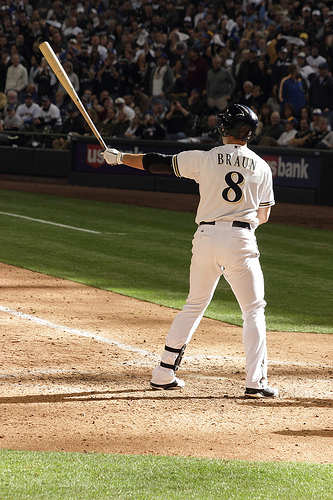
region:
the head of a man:
[212, 98, 262, 147]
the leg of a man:
[226, 249, 270, 384]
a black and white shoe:
[243, 382, 283, 399]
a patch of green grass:
[1, 446, 332, 498]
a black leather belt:
[195, 217, 254, 227]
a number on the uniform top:
[217, 167, 248, 204]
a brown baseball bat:
[37, 37, 113, 147]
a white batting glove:
[96, 142, 125, 169]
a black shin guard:
[158, 337, 190, 371]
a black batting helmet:
[212, 99, 259, 142]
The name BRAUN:
[213, 151, 265, 170]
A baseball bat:
[32, 36, 124, 171]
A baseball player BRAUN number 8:
[212, 151, 258, 212]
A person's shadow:
[0, 367, 322, 415]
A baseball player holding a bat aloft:
[32, 35, 296, 233]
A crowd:
[67, 0, 332, 92]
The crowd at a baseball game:
[1, 17, 332, 239]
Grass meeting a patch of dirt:
[5, 441, 331, 499]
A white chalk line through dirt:
[1, 306, 139, 373]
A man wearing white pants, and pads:
[147, 217, 279, 402]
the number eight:
[220, 168, 243, 203]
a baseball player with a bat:
[40, 42, 275, 397]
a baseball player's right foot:
[246, 384, 275, 400]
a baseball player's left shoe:
[150, 376, 186, 391]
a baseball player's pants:
[150, 220, 266, 389]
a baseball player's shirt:
[173, 141, 274, 223]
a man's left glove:
[98, 147, 121, 163]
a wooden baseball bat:
[37, 39, 108, 149]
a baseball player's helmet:
[216, 103, 257, 141]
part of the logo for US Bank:
[84, 142, 110, 169]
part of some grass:
[195, 458, 231, 490]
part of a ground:
[192, 404, 224, 435]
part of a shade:
[125, 382, 141, 395]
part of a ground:
[43, 403, 65, 429]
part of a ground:
[134, 406, 169, 461]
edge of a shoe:
[158, 374, 183, 400]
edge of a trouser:
[246, 372, 265, 389]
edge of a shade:
[265, 415, 297, 442]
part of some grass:
[175, 457, 194, 476]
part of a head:
[206, 51, 220, 67]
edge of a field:
[230, 448, 269, 477]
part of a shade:
[276, 428, 296, 437]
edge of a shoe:
[240, 390, 262, 403]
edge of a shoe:
[242, 397, 266, 412]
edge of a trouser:
[243, 380, 266, 391]